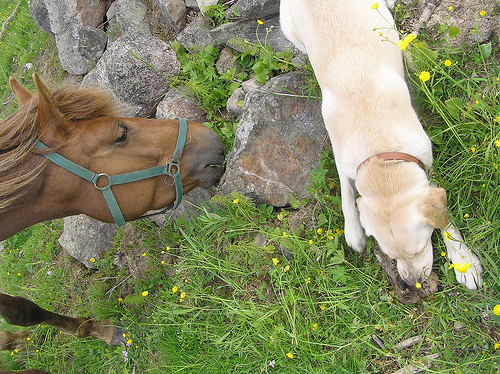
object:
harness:
[28, 116, 187, 225]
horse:
[0, 71, 229, 374]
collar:
[355, 150, 429, 176]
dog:
[278, 0, 484, 304]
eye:
[106, 121, 131, 145]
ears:
[8, 74, 36, 107]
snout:
[172, 118, 228, 190]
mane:
[0, 82, 120, 214]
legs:
[0, 292, 128, 346]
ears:
[417, 185, 449, 228]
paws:
[444, 253, 483, 292]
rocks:
[25, 0, 493, 271]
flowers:
[395, 32, 417, 51]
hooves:
[110, 315, 132, 346]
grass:
[174, 43, 226, 102]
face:
[378, 237, 435, 286]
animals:
[1, 71, 224, 350]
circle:
[93, 173, 112, 190]